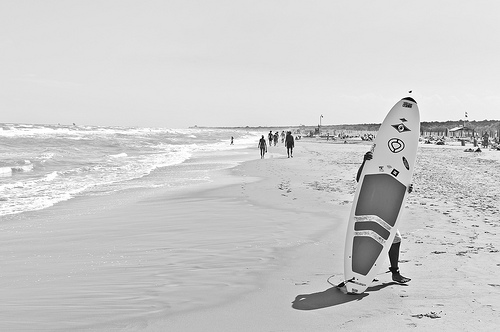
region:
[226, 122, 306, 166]
people walking on the beach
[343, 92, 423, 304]
person carrying a surf board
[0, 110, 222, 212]
white waves in the ocean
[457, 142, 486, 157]
people laying on the beach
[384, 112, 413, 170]
black markings on the white surfboard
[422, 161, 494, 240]
footprints on the sandy beach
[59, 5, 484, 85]
gray sky over the beach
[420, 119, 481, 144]
white building with gray roof on beach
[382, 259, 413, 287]
foot with an ankle bracelet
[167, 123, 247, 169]
a child on the shoreline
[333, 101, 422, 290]
white surfboard on beach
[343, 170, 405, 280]
black stomp pad on back of board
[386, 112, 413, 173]
logos on top of board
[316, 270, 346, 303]
portion of leash from board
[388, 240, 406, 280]
black leg portion of wet suit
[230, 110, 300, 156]
group of people walking on shore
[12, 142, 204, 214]
waves in the ocean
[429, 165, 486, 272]
foot prints in the sand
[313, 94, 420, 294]
man holding surfboard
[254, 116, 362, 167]
group of people hanging out on beach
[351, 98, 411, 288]
patterned long surf board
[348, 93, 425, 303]
person holding surf board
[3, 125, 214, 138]
wave breaking in ocean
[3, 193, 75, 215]
white foam from ocean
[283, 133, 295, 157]
person walking on beach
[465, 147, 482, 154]
person laying on beach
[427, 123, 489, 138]
building next to beach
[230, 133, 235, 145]
person standing in water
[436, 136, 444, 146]
people sitting in sand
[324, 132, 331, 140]
people standing in sand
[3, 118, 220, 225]
the water has waves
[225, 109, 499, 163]
people on the beach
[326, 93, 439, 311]
a person is carrying a surfboard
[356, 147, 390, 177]
a hand is on the surfboard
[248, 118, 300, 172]
people are walking on the sand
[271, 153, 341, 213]
the sand has footprints in it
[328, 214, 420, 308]
the surfboard is attached to the person's ankle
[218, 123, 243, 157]
a person is in the water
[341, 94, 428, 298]
the surfboard has a design on it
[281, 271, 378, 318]
a shadow in the sand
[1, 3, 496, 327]
Beach scene with surfers and tourists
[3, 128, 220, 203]
Waves crashing on the shoreline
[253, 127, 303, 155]
Many people walking on the beach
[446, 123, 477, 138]
A covered picnic area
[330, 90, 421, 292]
A person holding a surfboard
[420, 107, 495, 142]
A background of hills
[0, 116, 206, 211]
The ocean moving back and forth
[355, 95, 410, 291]
The surfboard has designs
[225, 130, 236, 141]
Someone going toward the water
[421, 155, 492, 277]
A sandy beach